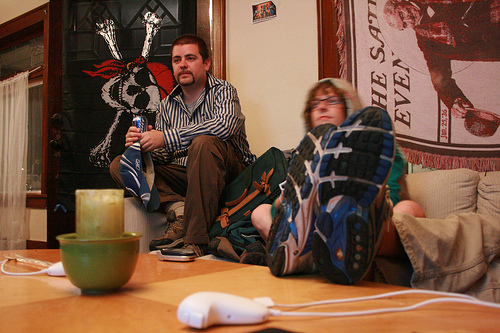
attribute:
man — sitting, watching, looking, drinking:
[128, 39, 240, 187]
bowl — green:
[59, 198, 140, 291]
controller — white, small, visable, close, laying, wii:
[178, 275, 266, 332]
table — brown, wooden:
[150, 255, 180, 316]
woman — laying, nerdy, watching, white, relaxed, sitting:
[295, 61, 363, 152]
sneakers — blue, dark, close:
[336, 115, 383, 271]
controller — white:
[174, 292, 279, 329]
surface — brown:
[5, 240, 483, 323]